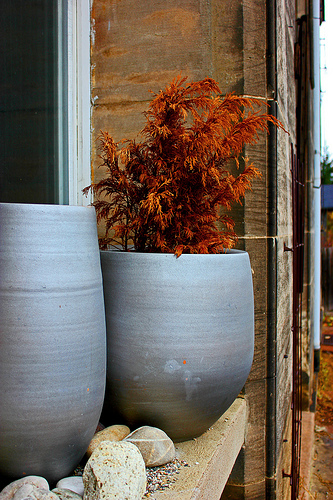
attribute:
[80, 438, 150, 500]
rock — white, porous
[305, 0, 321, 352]
pipe — silver, white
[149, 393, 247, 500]
ledge — wood, wooden, rocky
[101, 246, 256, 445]
planter — grey, empty, spotted, painted, silver, tall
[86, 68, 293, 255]
bush — orange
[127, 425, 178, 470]
stone — scratched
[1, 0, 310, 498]
building — wooden, wood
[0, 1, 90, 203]
window — white